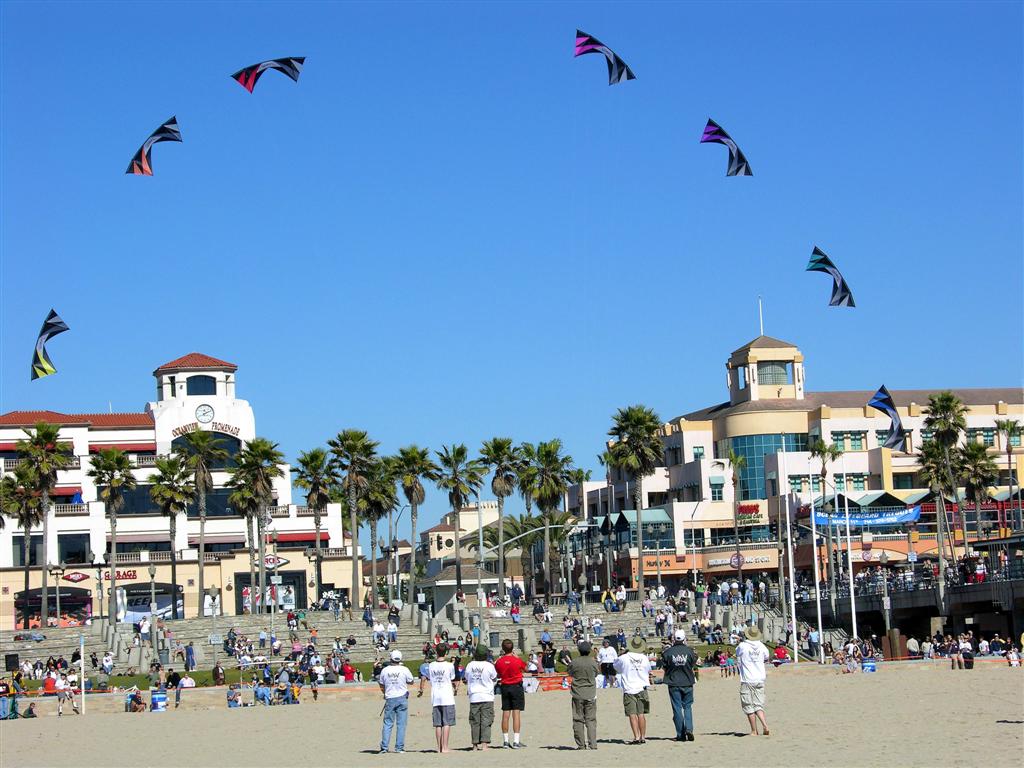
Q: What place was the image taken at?
A: It was taken at the stadium.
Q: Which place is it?
A: It is a stadium.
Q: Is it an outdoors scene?
A: Yes, it is outdoors.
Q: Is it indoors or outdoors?
A: It is outdoors.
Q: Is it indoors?
A: No, it is outdoors.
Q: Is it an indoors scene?
A: No, it is outdoors.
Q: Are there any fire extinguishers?
A: No, there are no fire extinguishers.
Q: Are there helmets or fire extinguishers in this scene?
A: No, there are no fire extinguishers or helmets.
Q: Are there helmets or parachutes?
A: No, there are no helmets or parachutes.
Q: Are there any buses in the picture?
A: No, there are no buses.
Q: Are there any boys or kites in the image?
A: Yes, there is a kite.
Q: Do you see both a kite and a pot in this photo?
A: No, there is a kite but no pots.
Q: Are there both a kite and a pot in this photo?
A: No, there is a kite but no pots.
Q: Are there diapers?
A: No, there are no diapers.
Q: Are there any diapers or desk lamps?
A: No, there are no diapers or desk lamps.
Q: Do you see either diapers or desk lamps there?
A: No, there are no diapers or desk lamps.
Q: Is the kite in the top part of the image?
A: Yes, the kite is in the top of the image.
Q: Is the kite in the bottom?
A: No, the kite is in the top of the image.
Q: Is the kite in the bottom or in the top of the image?
A: The kite is in the top of the image.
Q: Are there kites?
A: Yes, there is a kite.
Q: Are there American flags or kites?
A: Yes, there is a kite.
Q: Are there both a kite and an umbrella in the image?
A: No, there is a kite but no umbrellas.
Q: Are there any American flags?
A: No, there are no American flags.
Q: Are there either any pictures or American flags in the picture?
A: No, there are no American flags or pictures.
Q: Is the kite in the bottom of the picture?
A: No, the kite is in the top of the image.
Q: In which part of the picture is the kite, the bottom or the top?
A: The kite is in the top of the image.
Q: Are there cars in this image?
A: No, there are no cars.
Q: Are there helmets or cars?
A: No, there are no cars or helmets.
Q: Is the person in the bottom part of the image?
A: Yes, the person is in the bottom of the image.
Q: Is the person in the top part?
A: No, the person is in the bottom of the image.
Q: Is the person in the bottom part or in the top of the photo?
A: The person is in the bottom of the image.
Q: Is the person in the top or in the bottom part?
A: The person is in the bottom of the image.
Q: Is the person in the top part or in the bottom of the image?
A: The person is in the bottom of the image.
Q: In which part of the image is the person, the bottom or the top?
A: The person is in the bottom of the image.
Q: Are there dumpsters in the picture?
A: No, there are no dumpsters.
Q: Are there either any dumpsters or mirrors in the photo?
A: No, there are no dumpsters or mirrors.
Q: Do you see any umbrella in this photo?
A: No, there are no umbrellas.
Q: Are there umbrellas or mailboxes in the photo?
A: No, there are no umbrellas or mailboxes.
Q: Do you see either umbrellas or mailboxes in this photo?
A: No, there are no umbrellas or mailboxes.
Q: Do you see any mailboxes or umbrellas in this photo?
A: No, there are no umbrellas or mailboxes.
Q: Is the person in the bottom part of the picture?
A: Yes, the person is in the bottom of the image.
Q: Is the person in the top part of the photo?
A: No, the person is in the bottom of the image.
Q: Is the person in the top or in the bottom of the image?
A: The person is in the bottom of the image.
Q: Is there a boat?
A: No, there are no boats.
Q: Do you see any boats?
A: No, there are no boats.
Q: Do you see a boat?
A: No, there are no boats.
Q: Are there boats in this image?
A: No, there are no boats.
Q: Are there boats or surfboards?
A: No, there are no boats or surfboards.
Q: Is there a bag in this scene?
A: No, there are no bags.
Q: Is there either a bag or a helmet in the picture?
A: No, there are no bags or helmets.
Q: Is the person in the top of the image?
A: No, the person is in the bottom of the image.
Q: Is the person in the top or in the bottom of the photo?
A: The person is in the bottom of the image.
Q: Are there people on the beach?
A: Yes, there is a person on the beach.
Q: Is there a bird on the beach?
A: No, there is a person on the beach.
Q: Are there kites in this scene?
A: Yes, there is a kite.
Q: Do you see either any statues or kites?
A: Yes, there is a kite.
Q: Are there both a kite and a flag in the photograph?
A: No, there is a kite but no flags.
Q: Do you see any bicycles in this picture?
A: No, there are no bicycles.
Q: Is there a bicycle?
A: No, there are no bicycles.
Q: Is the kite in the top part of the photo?
A: Yes, the kite is in the top of the image.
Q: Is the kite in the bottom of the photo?
A: No, the kite is in the top of the image.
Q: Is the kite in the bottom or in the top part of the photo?
A: The kite is in the top of the image.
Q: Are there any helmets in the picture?
A: No, there are no helmets.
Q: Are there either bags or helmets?
A: No, there are no helmets or bags.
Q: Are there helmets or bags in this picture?
A: No, there are no helmets or bags.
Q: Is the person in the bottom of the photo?
A: Yes, the person is in the bottom of the image.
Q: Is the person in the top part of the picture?
A: No, the person is in the bottom of the image.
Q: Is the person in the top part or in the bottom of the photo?
A: The person is in the bottom of the image.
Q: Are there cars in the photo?
A: No, there are no cars.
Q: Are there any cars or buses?
A: No, there are no cars or buses.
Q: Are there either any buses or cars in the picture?
A: No, there are no cars or buses.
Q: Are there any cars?
A: No, there are no cars.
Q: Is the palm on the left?
A: Yes, the palm is on the left of the image.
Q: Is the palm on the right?
A: No, the palm is on the left of the image.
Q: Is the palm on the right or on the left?
A: The palm is on the left of the image.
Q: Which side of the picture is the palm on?
A: The palm is on the left of the image.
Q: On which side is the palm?
A: The palm is on the left of the image.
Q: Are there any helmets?
A: No, there are no helmets.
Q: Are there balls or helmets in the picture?
A: No, there are no helmets or balls.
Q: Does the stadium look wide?
A: Yes, the stadium is wide.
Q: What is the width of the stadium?
A: The stadium is wide.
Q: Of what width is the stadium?
A: The stadium is wide.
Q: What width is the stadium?
A: The stadium is wide.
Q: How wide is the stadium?
A: The stadium is wide.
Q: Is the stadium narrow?
A: No, the stadium is wide.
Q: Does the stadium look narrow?
A: No, the stadium is wide.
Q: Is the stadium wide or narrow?
A: The stadium is wide.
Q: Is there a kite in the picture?
A: Yes, there is a kite.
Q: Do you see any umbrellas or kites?
A: Yes, there is a kite.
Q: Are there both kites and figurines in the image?
A: No, there is a kite but no figurines.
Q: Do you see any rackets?
A: No, there are no rackets.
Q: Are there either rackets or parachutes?
A: No, there are no rackets or parachutes.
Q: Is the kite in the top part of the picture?
A: Yes, the kite is in the top of the image.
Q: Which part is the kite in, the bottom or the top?
A: The kite is in the top of the image.